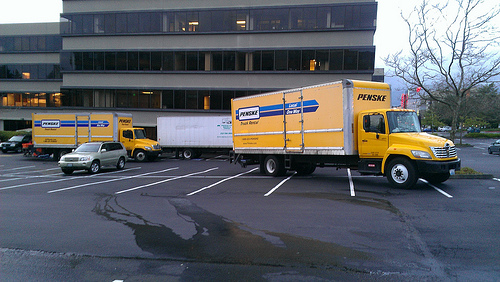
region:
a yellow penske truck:
[228, 75, 462, 195]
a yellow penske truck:
[26, 102, 165, 164]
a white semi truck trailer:
[152, 111, 239, 160]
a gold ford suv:
[60, 132, 126, 173]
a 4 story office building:
[3, 0, 377, 172]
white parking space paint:
[3, 162, 457, 200]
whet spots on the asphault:
[91, 184, 358, 278]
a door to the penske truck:
[276, 86, 306, 155]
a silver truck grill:
[430, 136, 460, 163]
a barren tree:
[395, 0, 495, 156]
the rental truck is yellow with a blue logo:
[226, 72, 461, 190]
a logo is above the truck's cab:
[341, 79, 458, 191]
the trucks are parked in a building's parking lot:
[4, 71, 467, 238]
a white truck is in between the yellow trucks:
[147, 109, 232, 159]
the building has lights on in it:
[10, 0, 422, 192]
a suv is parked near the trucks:
[50, 135, 132, 179]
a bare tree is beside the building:
[317, 0, 499, 154]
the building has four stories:
[0, 3, 385, 168]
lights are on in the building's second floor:
[4, 22, 78, 139]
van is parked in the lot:
[53, 135, 141, 182]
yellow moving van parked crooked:
[222, 78, 453, 190]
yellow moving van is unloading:
[29, 110, 167, 158]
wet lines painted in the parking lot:
[53, 172, 239, 194]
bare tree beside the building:
[390, 16, 485, 131]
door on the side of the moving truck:
[279, 90, 312, 152]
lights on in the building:
[1, 92, 58, 107]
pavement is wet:
[134, 222, 284, 275]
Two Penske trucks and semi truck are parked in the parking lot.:
[30, 70, 460, 190]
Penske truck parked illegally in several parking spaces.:
[220, 70, 470, 190]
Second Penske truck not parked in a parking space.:
[25, 107, 165, 167]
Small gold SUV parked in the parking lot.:
[55, 132, 132, 177]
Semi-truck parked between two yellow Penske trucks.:
[151, 110, 226, 161]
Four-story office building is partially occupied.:
[5, 2, 377, 73]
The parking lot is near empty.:
[7, 182, 483, 260]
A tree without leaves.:
[392, 6, 488, 91]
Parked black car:
[5, 130, 26, 151]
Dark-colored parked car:
[482, 135, 499, 157]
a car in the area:
[59, 135, 128, 172]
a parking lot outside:
[5, 163, 498, 217]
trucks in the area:
[25, 80, 457, 186]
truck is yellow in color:
[227, 78, 458, 182]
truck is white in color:
[153, 115, 238, 161]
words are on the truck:
[238, 107, 261, 122]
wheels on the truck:
[250, 149, 408, 192]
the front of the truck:
[357, 100, 456, 188]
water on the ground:
[93, 189, 391, 276]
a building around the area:
[6, 0, 381, 162]